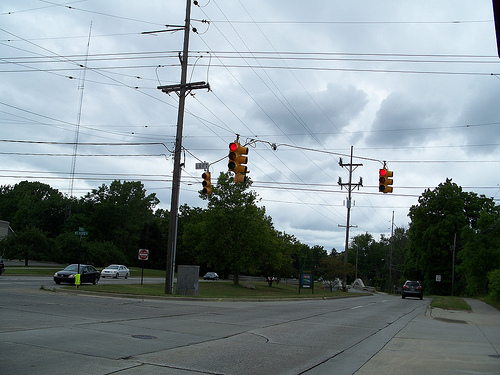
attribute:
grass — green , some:
[56, 260, 353, 301]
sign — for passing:
[297, 264, 313, 293]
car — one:
[55, 264, 101, 286]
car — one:
[102, 265, 131, 279]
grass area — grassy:
[427, 292, 472, 313]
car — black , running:
[53, 262, 101, 286]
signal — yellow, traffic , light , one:
[374, 159, 396, 202]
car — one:
[59, 259, 95, 286]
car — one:
[99, 257, 134, 282]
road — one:
[107, 272, 140, 285]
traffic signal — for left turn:
[201, 170, 212, 196]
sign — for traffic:
[127, 242, 154, 289]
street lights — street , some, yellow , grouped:
[193, 120, 409, 207]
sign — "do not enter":
[138, 244, 154, 270]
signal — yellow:
[221, 128, 256, 189]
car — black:
[400, 264, 436, 325]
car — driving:
[53, 262, 110, 292]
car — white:
[101, 255, 136, 280]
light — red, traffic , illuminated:
[355, 169, 397, 199]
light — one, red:
[223, 139, 252, 178]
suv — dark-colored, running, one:
[399, 278, 423, 303]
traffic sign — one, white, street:
[432, 271, 444, 288]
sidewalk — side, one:
[330, 260, 499, 347]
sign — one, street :
[137, 249, 149, 263]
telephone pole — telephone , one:
[336, 144, 363, 290]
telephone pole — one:
[143, 2, 212, 294]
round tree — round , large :
[2, 179, 70, 266]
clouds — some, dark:
[1, 2, 498, 248]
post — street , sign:
[75, 239, 84, 282]